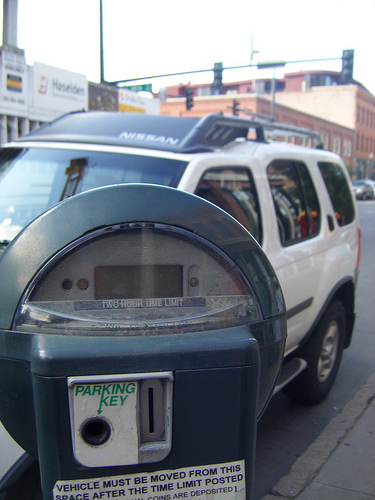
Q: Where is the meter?
A: Sidewalk.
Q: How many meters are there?
A: One.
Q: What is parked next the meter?
A: SUV.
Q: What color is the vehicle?
A: White.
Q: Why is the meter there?
A: To collect money.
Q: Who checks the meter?
A: Meter maid.